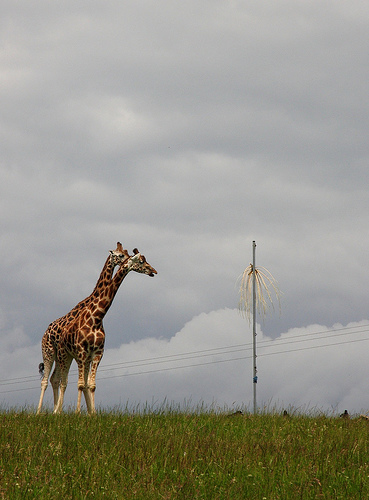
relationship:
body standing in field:
[36, 241, 158, 415] [4, 410, 365, 484]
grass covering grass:
[3, 413, 367, 459] [0, 395, 369, 499]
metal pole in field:
[252, 240, 257, 414] [4, 410, 365, 484]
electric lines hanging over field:
[126, 348, 223, 374] [4, 410, 365, 484]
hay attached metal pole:
[235, 261, 286, 328] [243, 288, 263, 409]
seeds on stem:
[52, 452, 66, 460] [51, 448, 59, 456]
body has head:
[36, 241, 158, 415] [103, 242, 134, 270]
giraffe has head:
[38, 311, 101, 406] [131, 247, 158, 277]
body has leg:
[36, 241, 158, 415] [75, 349, 94, 414]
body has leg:
[36, 241, 158, 415] [89, 346, 105, 413]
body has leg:
[36, 241, 158, 415] [34, 345, 57, 418]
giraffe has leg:
[53, 247, 157, 416] [75, 349, 94, 414]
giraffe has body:
[53, 247, 157, 416] [47, 313, 110, 365]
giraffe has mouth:
[53, 247, 157, 416] [145, 267, 161, 277]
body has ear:
[36, 241, 158, 415] [107, 252, 117, 261]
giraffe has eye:
[53, 247, 157, 416] [116, 252, 125, 260]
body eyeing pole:
[36, 241, 158, 415] [241, 235, 273, 420]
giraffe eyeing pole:
[53, 247, 157, 416] [249, 239, 263, 417]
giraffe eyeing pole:
[53, 247, 157, 416] [242, 237, 270, 418]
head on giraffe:
[126, 246, 160, 282] [53, 247, 157, 416]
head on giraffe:
[108, 241, 130, 267] [53, 247, 157, 416]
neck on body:
[89, 265, 125, 322] [36, 241, 158, 415]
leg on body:
[84, 345, 104, 416] [36, 241, 158, 415]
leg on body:
[75, 349, 94, 414] [36, 241, 158, 415]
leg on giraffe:
[51, 356, 72, 420] [53, 247, 157, 416]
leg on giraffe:
[47, 358, 67, 418] [53, 247, 157, 416]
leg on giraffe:
[34, 345, 57, 418] [53, 247, 157, 416]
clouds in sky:
[9, 305, 365, 414] [5, 1, 367, 425]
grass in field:
[1, 402, 367, 498] [4, 407, 357, 497]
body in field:
[36, 241, 158, 415] [4, 407, 357, 497]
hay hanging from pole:
[233, 255, 278, 316] [245, 237, 261, 419]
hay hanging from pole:
[235, 261, 286, 328] [251, 240, 257, 413]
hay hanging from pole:
[235, 261, 286, 328] [247, 231, 262, 410]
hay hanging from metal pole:
[233, 255, 278, 316] [252, 240, 257, 414]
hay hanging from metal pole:
[235, 261, 286, 328] [252, 240, 257, 414]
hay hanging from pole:
[235, 261, 286, 328] [247, 241, 260, 417]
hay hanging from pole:
[235, 261, 286, 328] [251, 236, 260, 417]